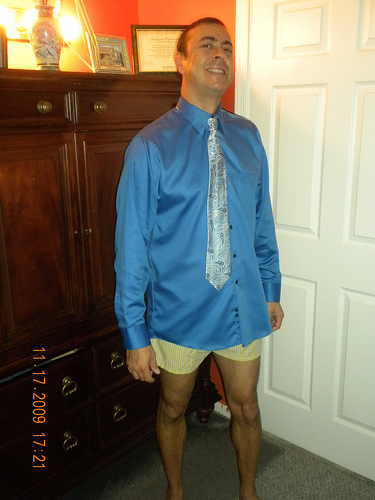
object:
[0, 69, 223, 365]
dresser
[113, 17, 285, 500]
man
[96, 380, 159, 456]
drawers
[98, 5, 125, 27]
board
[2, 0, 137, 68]
wall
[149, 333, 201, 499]
man's leg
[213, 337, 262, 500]
man's leg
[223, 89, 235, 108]
wall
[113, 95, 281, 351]
shirt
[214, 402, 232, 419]
base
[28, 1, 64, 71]
lamp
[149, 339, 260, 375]
shorts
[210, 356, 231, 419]
wall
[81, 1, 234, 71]
wall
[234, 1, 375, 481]
door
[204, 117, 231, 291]
silver tie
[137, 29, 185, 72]
paper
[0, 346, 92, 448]
cabinets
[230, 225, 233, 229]
buttons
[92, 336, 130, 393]
drawer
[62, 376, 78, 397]
handle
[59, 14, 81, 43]
light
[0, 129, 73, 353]
cabinet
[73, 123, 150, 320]
cabinet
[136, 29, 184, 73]
glass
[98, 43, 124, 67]
image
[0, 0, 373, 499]
room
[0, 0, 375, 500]
bedroom